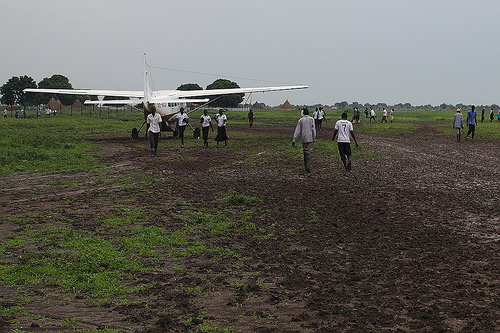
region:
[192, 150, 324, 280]
Brown mud on a field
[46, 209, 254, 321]
Green grass on a field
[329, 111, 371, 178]
Man with a 7 on his shirt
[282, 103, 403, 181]
Two men in a field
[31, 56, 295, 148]
Plane on a muddy field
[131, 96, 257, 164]
People walking in mud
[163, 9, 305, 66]
Cloudy, gray sky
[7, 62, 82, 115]
Green trees by a field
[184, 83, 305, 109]
White wing on a plane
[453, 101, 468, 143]
Person wearing a gray outfit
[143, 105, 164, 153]
a person walking on a field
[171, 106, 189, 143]
a person walking on a field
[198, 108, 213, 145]
a person walking on a field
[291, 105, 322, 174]
a person walking on a field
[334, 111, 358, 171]
a person walking on a field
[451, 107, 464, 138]
a person walking on a field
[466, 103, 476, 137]
a person walking on a field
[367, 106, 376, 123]
a person walking on a field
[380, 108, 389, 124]
a person walking on a field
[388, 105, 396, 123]
a person walking on a field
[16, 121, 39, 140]
this is the grass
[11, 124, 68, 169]
the grass is green in color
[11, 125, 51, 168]
the grass is short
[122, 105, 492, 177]
these are some people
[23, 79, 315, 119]
this is an airplane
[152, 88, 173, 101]
the airplane is white in color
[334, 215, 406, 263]
this is the ground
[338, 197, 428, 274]
the ground is muddy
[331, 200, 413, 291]
the mud is brown in color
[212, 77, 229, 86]
the leaves are green in color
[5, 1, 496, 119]
the sky is blue gray and clear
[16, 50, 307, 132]
a plane is parked on the field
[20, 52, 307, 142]
the plane has a propeller on the nose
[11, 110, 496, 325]
the primitive runway is dirt and weeds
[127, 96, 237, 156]
people are walking away from the plane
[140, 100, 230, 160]
the people have white shirts on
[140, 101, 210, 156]
the people have black pants on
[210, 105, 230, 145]
the lady has a black skirt on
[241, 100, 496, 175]
people are walking on the landing field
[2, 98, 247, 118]
a fence is near the plane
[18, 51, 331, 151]
a white plane in a field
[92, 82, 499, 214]
several people walking in a field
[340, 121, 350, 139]
number 7 on back of shirt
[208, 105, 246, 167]
a woman in a black skirt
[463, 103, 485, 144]
a man in a blue shirt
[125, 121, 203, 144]
two wheels of the plane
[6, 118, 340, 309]
grassy patches on the dirt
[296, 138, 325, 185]
brown pants on a man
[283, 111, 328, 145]
long sleeved gray shirt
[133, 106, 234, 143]
four girls in white shirts